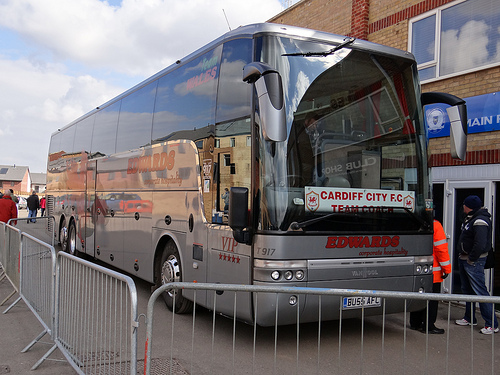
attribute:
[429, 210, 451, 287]
coat — orange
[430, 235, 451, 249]
stripe — silver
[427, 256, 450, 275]
stripe — silver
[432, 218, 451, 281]
jacket — orange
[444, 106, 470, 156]
mirror — large, silver, black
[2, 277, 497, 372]
rail — metal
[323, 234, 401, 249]
company letters — red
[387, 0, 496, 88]
windows — dark shaded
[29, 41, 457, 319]
bus — gated, side mirror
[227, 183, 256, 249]
mirror — secondary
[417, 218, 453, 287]
jacket — orange, white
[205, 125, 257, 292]
door — closed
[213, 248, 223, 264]
star — red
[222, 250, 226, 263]
star — red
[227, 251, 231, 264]
star — red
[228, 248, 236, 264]
star — red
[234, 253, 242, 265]
star — red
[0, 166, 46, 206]
houses — few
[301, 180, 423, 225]
sign — red, white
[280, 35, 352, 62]
wiper — buses windshield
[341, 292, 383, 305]
license plate — bus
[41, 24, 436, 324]
bus — fenced in, large, silver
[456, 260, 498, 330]
jeans — blue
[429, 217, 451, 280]
safety jacket — orange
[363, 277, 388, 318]
license plate — white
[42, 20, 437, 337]
passenger bus — large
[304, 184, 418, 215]
advertisement — business, banner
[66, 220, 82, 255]
tire — rear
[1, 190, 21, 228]
coat — red, winter coat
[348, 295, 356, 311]
letter — black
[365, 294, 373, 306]
letter — black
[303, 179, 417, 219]
sign — destination, bus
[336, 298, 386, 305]
number — bus, identification